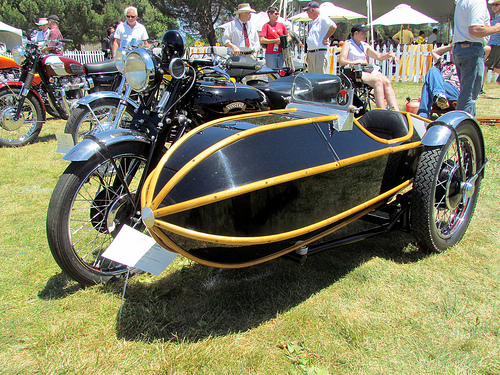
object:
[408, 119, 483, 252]
back tire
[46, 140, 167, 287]
wheel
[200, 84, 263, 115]
gas tank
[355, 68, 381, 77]
shorts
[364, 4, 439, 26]
umbrella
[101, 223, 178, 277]
sign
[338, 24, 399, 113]
person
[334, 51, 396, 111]
wheelchair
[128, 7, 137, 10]
hairline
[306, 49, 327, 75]
pants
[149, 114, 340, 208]
lines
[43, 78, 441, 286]
motorcycle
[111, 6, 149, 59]
man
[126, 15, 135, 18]
glasses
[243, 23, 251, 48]
tie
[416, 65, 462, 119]
jeans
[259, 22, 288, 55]
shirt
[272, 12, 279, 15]
glasses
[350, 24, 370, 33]
hat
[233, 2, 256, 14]
hat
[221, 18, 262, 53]
shirt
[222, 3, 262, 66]
man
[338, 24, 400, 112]
woman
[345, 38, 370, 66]
shirt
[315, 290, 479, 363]
grass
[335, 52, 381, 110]
chair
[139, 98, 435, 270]
sidecar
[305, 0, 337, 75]
man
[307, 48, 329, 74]
khakis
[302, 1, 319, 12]
cap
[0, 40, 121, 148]
motorcycle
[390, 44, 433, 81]
table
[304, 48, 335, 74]
table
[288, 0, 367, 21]
umbrella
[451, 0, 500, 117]
man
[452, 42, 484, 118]
jeans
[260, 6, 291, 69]
person